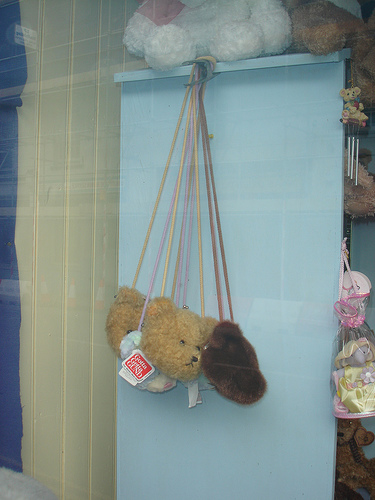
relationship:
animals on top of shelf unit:
[122, 1, 373, 66] [107, 45, 374, 496]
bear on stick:
[338, 84, 369, 119] [340, 117, 366, 125]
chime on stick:
[345, 135, 350, 177] [339, 115, 365, 127]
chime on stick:
[350, 133, 355, 180] [339, 115, 365, 127]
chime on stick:
[354, 137, 359, 184] [339, 115, 365, 127]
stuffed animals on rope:
[108, 284, 266, 403] [130, 54, 241, 329]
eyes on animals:
[180, 340, 200, 351] [104, 279, 271, 405]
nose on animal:
[188, 352, 198, 363] [105, 287, 219, 393]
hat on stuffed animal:
[316, 306, 370, 360] [95, 267, 239, 399]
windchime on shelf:
[99, 53, 268, 406] [110, 49, 351, 87]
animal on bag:
[313, 299, 374, 430] [324, 368, 374, 407]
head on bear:
[200, 319, 266, 406] [197, 319, 268, 407]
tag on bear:
[119, 348, 155, 386] [119, 290, 216, 392]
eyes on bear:
[175, 333, 202, 349] [139, 297, 268, 403]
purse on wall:
[79, 283, 197, 368] [28, 90, 315, 258]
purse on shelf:
[104, 289, 217, 392] [114, 28, 348, 90]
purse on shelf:
[136, 292, 217, 384] [114, 28, 348, 90]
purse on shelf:
[199, 315, 272, 408] [114, 28, 348, 90]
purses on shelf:
[87, 46, 272, 408] [111, 45, 374, 86]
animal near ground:
[99, 268, 210, 397] [2, 458, 83, 494]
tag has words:
[123, 351, 146, 379] [124, 351, 147, 370]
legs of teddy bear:
[106, 319, 135, 355] [144, 1, 278, 57]